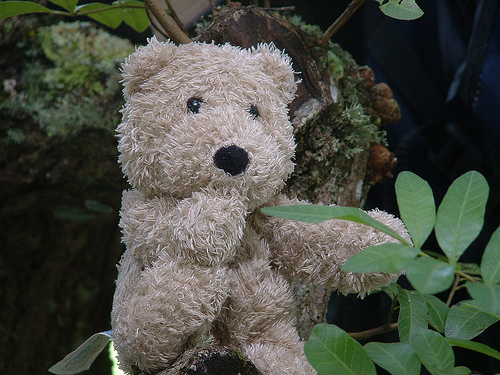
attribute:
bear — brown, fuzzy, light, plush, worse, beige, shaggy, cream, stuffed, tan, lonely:
[115, 47, 404, 365]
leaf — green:
[400, 166, 431, 245]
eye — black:
[179, 79, 205, 117]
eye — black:
[241, 95, 267, 116]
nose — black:
[217, 144, 263, 168]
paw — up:
[184, 193, 267, 264]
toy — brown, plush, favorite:
[111, 31, 413, 373]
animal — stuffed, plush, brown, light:
[112, 30, 394, 374]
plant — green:
[347, 202, 497, 374]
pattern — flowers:
[381, 24, 483, 172]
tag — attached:
[47, 327, 144, 374]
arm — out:
[143, 195, 251, 264]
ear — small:
[127, 39, 170, 75]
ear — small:
[252, 39, 294, 94]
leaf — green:
[269, 200, 388, 238]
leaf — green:
[352, 247, 419, 266]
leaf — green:
[451, 170, 487, 264]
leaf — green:
[390, 285, 426, 362]